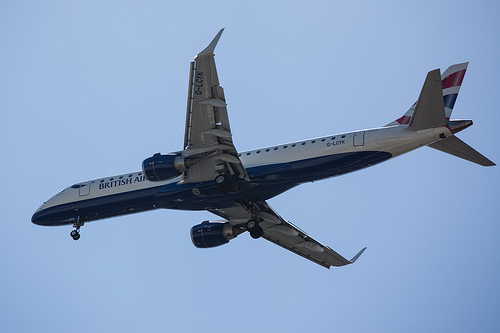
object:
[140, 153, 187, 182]
engine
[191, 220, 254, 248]
motor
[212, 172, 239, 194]
landing gear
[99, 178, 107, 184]
windows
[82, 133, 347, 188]
row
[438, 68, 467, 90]
stripe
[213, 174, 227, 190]
wheel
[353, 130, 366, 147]
door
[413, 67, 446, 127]
wing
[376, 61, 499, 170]
tail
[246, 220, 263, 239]
wheel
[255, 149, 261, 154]
window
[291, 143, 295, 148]
window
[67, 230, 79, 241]
wheel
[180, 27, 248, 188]
wing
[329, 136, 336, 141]
window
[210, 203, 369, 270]
wing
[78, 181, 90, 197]
door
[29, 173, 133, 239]
front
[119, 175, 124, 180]
window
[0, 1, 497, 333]
air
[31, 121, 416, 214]
side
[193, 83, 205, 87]
number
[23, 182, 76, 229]
nose